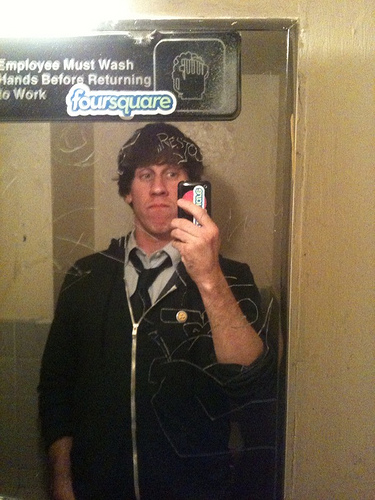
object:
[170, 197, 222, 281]
hand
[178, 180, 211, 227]
phone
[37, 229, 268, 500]
sweater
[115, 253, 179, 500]
zipper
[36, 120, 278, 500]
man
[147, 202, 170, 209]
mouth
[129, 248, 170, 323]
tie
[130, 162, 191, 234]
face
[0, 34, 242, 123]
sign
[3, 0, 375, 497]
wall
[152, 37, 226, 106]
symbol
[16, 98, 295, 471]
writing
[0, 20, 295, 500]
mirror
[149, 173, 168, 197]
nose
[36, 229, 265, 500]
jacket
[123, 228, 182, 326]
shirt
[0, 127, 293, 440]
scratches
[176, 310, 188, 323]
button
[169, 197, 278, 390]
arm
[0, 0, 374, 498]
bathroom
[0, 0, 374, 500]
picture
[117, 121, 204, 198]
hair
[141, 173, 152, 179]
eyes